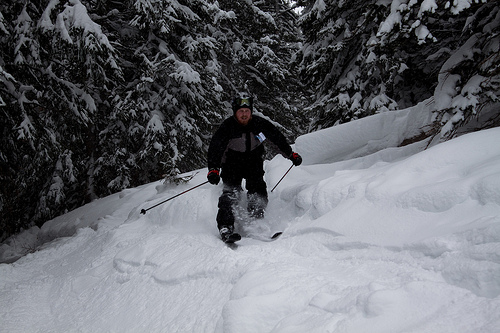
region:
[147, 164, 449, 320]
the snow is deep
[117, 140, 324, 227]
the man is holding ski poles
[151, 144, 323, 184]
the man is wearing gloves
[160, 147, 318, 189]
the gloves are black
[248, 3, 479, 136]
the trees are filled with snow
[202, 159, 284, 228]
the pants are black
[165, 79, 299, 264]
the man is wearing skis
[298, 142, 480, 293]
the snow is fluffy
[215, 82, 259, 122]
the man is wearing a hood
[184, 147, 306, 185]
the gloves have red on them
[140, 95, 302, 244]
A man skiing in snow.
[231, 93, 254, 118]
A black ski hat.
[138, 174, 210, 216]
A black ski pole.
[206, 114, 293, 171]
Black and gray jacket.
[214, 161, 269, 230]
Pair of black pants.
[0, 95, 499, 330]
An area of snow.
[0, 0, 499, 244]
Background of snow covered trees.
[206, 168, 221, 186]
Black and red glove.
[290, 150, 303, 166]
A black snow glove.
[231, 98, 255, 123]
A human male head.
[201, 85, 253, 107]
helmet on the head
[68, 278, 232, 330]
snwo on the ground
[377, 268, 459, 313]
the snow is white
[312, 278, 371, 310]
tracks on the snow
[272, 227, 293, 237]
snow on the ski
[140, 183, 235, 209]
ski pole in hand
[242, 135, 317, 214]
ski polke in hand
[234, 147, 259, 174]
the jacket is black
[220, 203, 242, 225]
the pants are black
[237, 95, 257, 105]
the helmet is black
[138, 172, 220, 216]
the skiers black ski pole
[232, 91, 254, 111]
the skiers black ski helmet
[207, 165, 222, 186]
the skiers black and red ski gloves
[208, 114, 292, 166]
a black and brown ski jacket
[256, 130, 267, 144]
the ski lift ticket attached to the jacket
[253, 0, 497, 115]
snow covered pine trees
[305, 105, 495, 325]
snow drift pile of snow on the snow bank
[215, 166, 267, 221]
a black pair of ski pants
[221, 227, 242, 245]
a black snow ski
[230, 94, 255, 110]
a winter knit cap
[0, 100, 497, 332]
snow covered ground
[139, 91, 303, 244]
a man wearing a black and gray snow suit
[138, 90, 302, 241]
a man standing on skis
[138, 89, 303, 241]
a man holding ski poles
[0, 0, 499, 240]
trees covered with snow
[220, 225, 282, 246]
black colored skis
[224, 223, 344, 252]
dark shadows on the ground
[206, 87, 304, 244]
a man wearing black colored gloves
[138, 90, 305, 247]
the man is skiing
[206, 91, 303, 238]
the man is wearing a toboggan